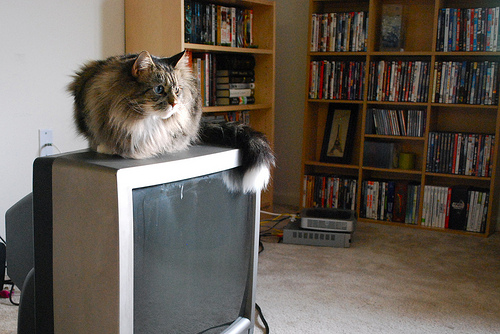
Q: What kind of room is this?
A: Living room.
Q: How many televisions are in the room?
A: One.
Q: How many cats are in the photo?
A: One.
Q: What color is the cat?
A: Tan, black and white.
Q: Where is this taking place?
A: In a multimedia room.